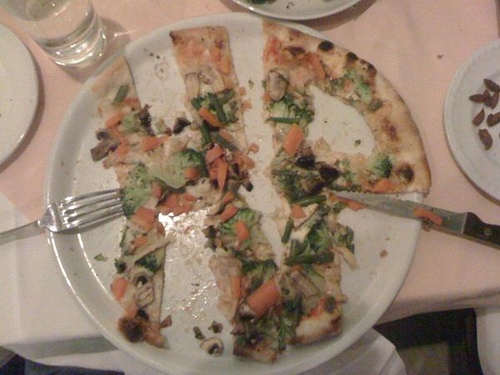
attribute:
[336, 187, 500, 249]
knife — metal, silver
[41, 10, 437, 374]
plate — white, round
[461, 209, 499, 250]
handle — black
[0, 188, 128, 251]
fork — silver, metal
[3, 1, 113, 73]
glass — clear, water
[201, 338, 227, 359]
crumb — small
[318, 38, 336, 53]
spot — black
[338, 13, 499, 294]
table — pink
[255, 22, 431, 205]
slice — small, pizza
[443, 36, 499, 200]
plate — white